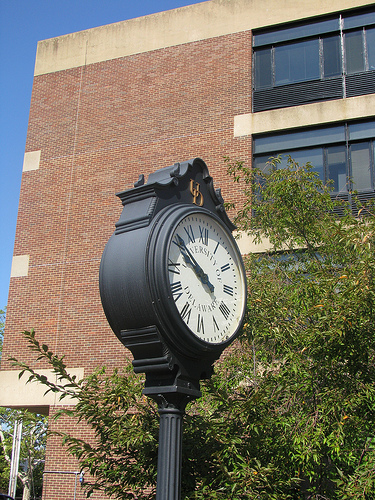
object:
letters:
[189, 178, 200, 197]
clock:
[163, 207, 248, 350]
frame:
[95, 156, 248, 398]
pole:
[155, 390, 185, 499]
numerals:
[213, 241, 220, 254]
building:
[0, 0, 374, 498]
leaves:
[267, 181, 272, 188]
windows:
[269, 33, 326, 90]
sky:
[0, 0, 203, 368]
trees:
[354, 394, 375, 491]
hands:
[179, 246, 215, 294]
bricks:
[161, 76, 167, 83]